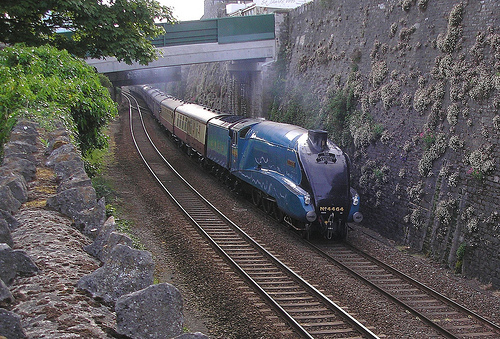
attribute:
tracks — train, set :
[227, 233, 363, 333]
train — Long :
[137, 71, 371, 235]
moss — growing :
[408, 66, 445, 116]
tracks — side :
[173, 170, 284, 287]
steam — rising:
[244, 60, 350, 168]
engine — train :
[261, 123, 372, 241]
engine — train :
[274, 126, 367, 226]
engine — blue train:
[334, 91, 355, 112]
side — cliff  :
[20, 106, 187, 289]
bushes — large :
[4, 1, 126, 161]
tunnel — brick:
[57, 13, 287, 83]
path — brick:
[9, 123, 115, 336]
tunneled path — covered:
[51, 12, 287, 72]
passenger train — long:
[129, 78, 362, 242]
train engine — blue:
[205, 113, 363, 237]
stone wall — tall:
[1, 105, 210, 336]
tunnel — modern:
[51, 13, 289, 74]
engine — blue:
[204, 112, 363, 240]